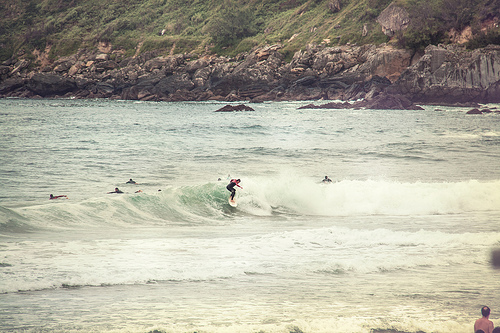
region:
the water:
[272, 163, 343, 318]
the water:
[300, 189, 352, 284]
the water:
[292, 222, 360, 331]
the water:
[340, 234, 362, 321]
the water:
[331, 231, 369, 299]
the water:
[318, 233, 352, 320]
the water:
[310, 259, 345, 318]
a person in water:
[211, 140, 268, 223]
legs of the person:
[217, 195, 242, 205]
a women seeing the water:
[469, 290, 499, 331]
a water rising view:
[46, 177, 498, 237]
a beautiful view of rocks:
[63, 25, 489, 140]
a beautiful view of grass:
[148, 7, 494, 54]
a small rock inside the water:
[188, 92, 366, 136]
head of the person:
[471, 296, 498, 315]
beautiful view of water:
[44, 115, 379, 328]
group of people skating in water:
[30, 90, 495, 286]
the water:
[48, 107, 173, 324]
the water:
[122, 192, 169, 274]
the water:
[54, 172, 144, 301]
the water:
[159, 185, 285, 315]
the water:
[103, 154, 214, 316]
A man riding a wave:
[214, 174, 246, 207]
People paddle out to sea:
[47, 170, 156, 206]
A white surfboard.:
[226, 195, 240, 207]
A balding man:
[479, 302, 489, 317]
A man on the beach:
[463, 304, 498, 331]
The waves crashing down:
[275, 179, 423, 225]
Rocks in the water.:
[208, 102, 266, 117]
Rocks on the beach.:
[22, 48, 497, 101]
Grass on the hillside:
[137, 9, 362, 40]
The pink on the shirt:
[232, 178, 244, 188]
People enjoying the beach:
[35, 143, 460, 239]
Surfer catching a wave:
[202, 166, 252, 232]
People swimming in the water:
[35, 165, 205, 220]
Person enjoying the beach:
[460, 290, 495, 330]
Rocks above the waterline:
[210, 90, 255, 125]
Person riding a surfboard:
[210, 160, 245, 220]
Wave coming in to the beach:
[340, 165, 495, 225]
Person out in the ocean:
[305, 165, 350, 190]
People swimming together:
[40, 165, 175, 215]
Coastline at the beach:
[50, 31, 190, 117]